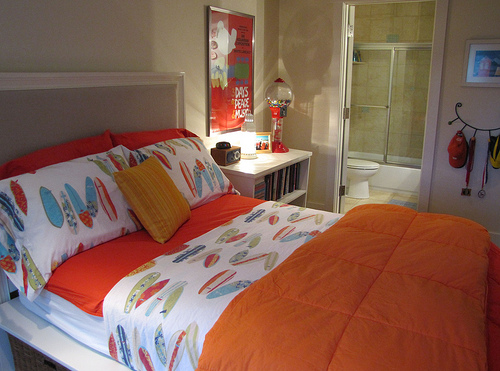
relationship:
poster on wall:
[206, 1, 268, 133] [32, 20, 81, 49]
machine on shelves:
[266, 69, 303, 150] [238, 154, 296, 175]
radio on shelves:
[215, 140, 245, 167] [238, 154, 296, 175]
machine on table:
[266, 69, 303, 150] [260, 153, 316, 161]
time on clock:
[233, 152, 240, 164] [206, 142, 239, 158]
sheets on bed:
[214, 246, 260, 270] [7, 107, 459, 344]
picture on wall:
[454, 34, 498, 92] [32, 20, 81, 49]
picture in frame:
[454, 34, 498, 92] [442, 34, 494, 50]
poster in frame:
[206, 1, 268, 133] [442, 34, 494, 50]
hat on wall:
[447, 146, 471, 172] [32, 20, 81, 49]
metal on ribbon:
[463, 141, 492, 198] [461, 130, 492, 147]